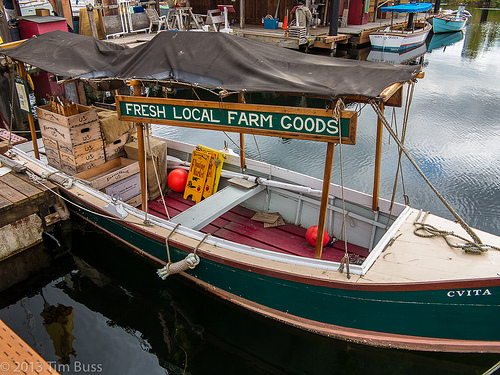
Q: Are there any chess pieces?
A: No, there are no chess pieces.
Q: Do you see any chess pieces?
A: No, there are no chess pieces.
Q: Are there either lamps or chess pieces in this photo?
A: No, there are no chess pieces or lamps.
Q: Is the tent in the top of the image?
A: Yes, the tent is in the top of the image.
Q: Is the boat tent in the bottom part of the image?
A: No, the tent is in the top of the image.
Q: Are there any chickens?
A: No, there are no chickens.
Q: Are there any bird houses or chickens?
A: No, there are no chickens or bird houses.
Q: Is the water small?
A: Yes, the water is small.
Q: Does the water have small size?
A: Yes, the water is small.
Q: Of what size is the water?
A: The water is small.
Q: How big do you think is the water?
A: The water is small.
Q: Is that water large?
A: No, the water is small.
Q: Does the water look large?
A: No, the water is small.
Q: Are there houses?
A: No, there are no houses.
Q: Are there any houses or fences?
A: No, there are no houses or fences.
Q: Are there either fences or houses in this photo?
A: No, there are no houses or fences.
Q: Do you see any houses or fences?
A: No, there are no houses or fences.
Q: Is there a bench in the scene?
A: Yes, there is a bench.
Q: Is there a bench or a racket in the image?
A: Yes, there is a bench.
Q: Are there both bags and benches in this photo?
A: No, there is a bench but no bags.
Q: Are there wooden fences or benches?
A: Yes, there is a wood bench.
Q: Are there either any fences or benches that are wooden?
A: Yes, the bench is wooden.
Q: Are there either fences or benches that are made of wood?
A: Yes, the bench is made of wood.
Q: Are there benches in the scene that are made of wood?
A: Yes, there is a bench that is made of wood.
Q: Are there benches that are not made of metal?
A: Yes, there is a bench that is made of wood.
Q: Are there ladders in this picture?
A: No, there are no ladders.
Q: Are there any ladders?
A: No, there are no ladders.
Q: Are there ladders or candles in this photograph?
A: No, there are no ladders or candles.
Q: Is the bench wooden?
A: Yes, the bench is wooden.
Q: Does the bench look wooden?
A: Yes, the bench is wooden.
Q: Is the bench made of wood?
A: Yes, the bench is made of wood.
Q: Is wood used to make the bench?
A: Yes, the bench is made of wood.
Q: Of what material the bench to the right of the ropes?
A: The bench is made of wood.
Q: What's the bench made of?
A: The bench is made of wood.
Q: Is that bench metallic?
A: No, the bench is wooden.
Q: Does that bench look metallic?
A: No, the bench is wooden.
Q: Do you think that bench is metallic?
A: No, the bench is wooden.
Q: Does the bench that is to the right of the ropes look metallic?
A: No, the bench is wooden.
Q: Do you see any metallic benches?
A: No, there is a bench but it is wooden.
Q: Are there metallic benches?
A: No, there is a bench but it is wooden.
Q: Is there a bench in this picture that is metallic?
A: No, there is a bench but it is wooden.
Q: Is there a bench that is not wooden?
A: No, there is a bench but it is wooden.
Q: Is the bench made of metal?
A: No, the bench is made of wood.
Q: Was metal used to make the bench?
A: No, the bench is made of wood.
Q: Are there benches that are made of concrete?
A: No, there is a bench but it is made of wood.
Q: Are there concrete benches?
A: No, there is a bench but it is made of wood.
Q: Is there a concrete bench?
A: No, there is a bench but it is made of wood.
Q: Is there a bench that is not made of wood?
A: No, there is a bench but it is made of wood.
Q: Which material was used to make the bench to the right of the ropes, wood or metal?
A: The bench is made of wood.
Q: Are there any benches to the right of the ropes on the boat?
A: Yes, there is a bench to the right of the ropes.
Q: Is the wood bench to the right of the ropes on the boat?
A: Yes, the bench is to the right of the ropes.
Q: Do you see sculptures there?
A: No, there are no sculptures.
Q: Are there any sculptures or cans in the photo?
A: No, there are no sculptures or cans.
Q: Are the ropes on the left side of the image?
A: Yes, the ropes are on the left of the image.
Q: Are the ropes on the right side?
A: No, the ropes are on the left of the image.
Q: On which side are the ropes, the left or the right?
A: The ropes are on the left of the image.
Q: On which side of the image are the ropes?
A: The ropes are on the left of the image.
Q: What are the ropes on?
A: The ropes are on the boat.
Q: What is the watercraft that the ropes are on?
A: The watercraft is a boat.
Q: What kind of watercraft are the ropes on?
A: The ropes are on the boat.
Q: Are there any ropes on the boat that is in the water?
A: Yes, there are ropes on the boat.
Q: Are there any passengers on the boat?
A: No, there are ropes on the boat.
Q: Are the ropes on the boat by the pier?
A: Yes, the ropes are on the boat.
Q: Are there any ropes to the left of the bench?
A: Yes, there are ropes to the left of the bench.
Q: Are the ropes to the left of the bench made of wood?
A: Yes, the ropes are to the left of the bench.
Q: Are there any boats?
A: Yes, there is a boat.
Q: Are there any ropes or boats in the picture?
A: Yes, there is a boat.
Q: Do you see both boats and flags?
A: No, there is a boat but no flags.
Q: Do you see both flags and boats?
A: No, there is a boat but no flags.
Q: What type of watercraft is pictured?
A: The watercraft is a boat.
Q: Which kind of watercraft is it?
A: The watercraft is a boat.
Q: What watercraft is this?
A: This is a boat.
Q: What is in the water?
A: The boat is in the water.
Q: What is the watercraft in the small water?
A: The watercraft is a boat.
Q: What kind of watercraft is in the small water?
A: The watercraft is a boat.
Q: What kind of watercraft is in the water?
A: The watercraft is a boat.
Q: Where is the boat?
A: The boat is in the water.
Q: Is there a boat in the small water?
A: Yes, there is a boat in the water.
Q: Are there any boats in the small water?
A: Yes, there is a boat in the water.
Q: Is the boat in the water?
A: Yes, the boat is in the water.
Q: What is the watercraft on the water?
A: The watercraft is a boat.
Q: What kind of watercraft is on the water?
A: The watercraft is a boat.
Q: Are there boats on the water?
A: Yes, there is a boat on the water.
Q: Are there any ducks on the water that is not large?
A: No, there is a boat on the water.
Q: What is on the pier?
A: The boat is on the pier.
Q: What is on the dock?
A: The boat is on the pier.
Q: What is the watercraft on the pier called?
A: The watercraft is a boat.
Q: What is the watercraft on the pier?
A: The watercraft is a boat.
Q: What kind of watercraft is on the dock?
A: The watercraft is a boat.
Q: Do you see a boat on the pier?
A: Yes, there is a boat on the pier.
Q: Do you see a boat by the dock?
A: Yes, there is a boat by the dock.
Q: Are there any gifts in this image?
A: No, there are no gifts.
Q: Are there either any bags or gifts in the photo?
A: No, there are no gifts or bags.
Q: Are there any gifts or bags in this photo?
A: No, there are no gifts or bags.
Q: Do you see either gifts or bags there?
A: No, there are no gifts or bags.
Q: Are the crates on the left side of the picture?
A: Yes, the crates are on the left of the image.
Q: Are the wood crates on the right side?
A: No, the crates are on the left of the image.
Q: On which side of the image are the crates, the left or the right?
A: The crates are on the left of the image.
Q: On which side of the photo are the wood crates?
A: The crates are on the left of the image.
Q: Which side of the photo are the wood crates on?
A: The crates are on the left of the image.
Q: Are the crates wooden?
A: Yes, the crates are wooden.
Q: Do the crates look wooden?
A: Yes, the crates are wooden.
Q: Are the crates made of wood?
A: Yes, the crates are made of wood.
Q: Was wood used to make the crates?
A: Yes, the crates are made of wood.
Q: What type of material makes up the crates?
A: The crates are made of wood.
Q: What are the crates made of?
A: The crates are made of wood.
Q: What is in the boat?
A: The crates are in the boat.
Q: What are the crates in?
A: The crates are in the boat.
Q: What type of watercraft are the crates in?
A: The crates are in the boat.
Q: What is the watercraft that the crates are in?
A: The watercraft is a boat.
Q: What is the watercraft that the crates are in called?
A: The watercraft is a boat.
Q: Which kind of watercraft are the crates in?
A: The crates are in the boat.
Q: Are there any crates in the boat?
A: Yes, there are crates in the boat.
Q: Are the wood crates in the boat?
A: Yes, the crates are in the boat.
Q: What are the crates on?
A: The crates are on the boat.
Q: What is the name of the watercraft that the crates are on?
A: The watercraft is a boat.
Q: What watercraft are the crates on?
A: The crates are on the boat.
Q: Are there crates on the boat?
A: Yes, there are crates on the boat.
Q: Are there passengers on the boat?
A: No, there are crates on the boat.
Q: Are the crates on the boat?
A: Yes, the crates are on the boat.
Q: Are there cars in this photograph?
A: No, there are no cars.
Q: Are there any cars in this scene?
A: No, there are no cars.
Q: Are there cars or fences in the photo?
A: No, there are no cars or fences.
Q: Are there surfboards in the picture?
A: No, there are no surfboards.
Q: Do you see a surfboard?
A: No, there are no surfboards.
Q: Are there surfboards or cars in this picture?
A: No, there are no surfboards or cars.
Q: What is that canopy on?
A: The canopy is on the boat.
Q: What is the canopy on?
A: The canopy is on the boat.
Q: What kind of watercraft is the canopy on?
A: The canopy is on the boat.